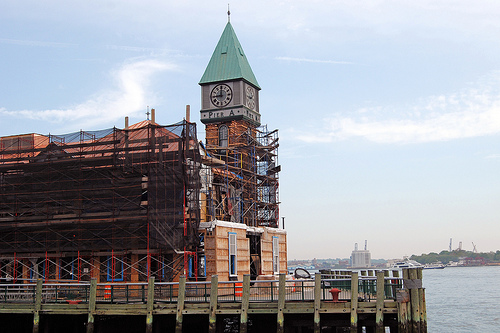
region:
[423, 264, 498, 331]
a body of water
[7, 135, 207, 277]
construction on the side of a building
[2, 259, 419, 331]
a pier in front of a building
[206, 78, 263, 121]
a clock on a building tower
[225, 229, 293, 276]
two building windows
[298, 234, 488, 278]
building across the body of water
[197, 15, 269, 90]
a green tower roof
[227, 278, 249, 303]
a orange and white striped construction barrel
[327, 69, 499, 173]
a white cloud in the sky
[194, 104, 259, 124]
a sign saying Pier A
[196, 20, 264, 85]
pointed green rooftop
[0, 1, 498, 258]
clear blue sky with some clouds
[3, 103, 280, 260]
scaffolding across a building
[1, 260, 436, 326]
surrounding wooden dock and fence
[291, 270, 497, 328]
blue clear waterfront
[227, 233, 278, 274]
two windows at front of building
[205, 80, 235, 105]
clock in green tower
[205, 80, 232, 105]
black Roman numerals on clock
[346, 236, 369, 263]
white building in distance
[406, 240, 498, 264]
green trees in background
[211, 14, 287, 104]
pale green steeple roof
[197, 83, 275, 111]
white and gray double clock head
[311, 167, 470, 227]
clear light blue sky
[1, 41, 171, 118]
swirly white cloud sky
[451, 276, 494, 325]
light gray ocean front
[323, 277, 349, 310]
bright red metal hydrant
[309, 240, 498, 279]
city in the distant behind river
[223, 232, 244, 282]
large white rectangular windows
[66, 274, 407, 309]
wooded docking water pier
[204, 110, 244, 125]
Pier A labeled Pier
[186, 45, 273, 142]
Clock is on the tower.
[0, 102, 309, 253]
Building is under construction.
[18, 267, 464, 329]
Dock is above the water.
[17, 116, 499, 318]
Building is on the dock.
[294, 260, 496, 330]
Water flows under the dock.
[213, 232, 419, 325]
There are no people on the dock.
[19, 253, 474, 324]
The dock is made of wood.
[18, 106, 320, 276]
A scaffolding is against the building.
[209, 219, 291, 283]
There are windows on the front of the building.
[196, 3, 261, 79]
A lightening rod is on top of the building.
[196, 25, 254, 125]
Clock tower with green roof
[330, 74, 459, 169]
Blue sky with dissolving clouds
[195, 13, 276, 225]
Construction scaffolding around clock tower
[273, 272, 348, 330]
Wooden fence at the pier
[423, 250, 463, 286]
Boat in distance on calm water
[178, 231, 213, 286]
Blue construction tape around window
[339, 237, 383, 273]
Large building in the distance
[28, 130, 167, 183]
Construction fences on side of building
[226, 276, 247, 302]
Orange and white construction barrel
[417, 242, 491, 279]
Green trees across the water